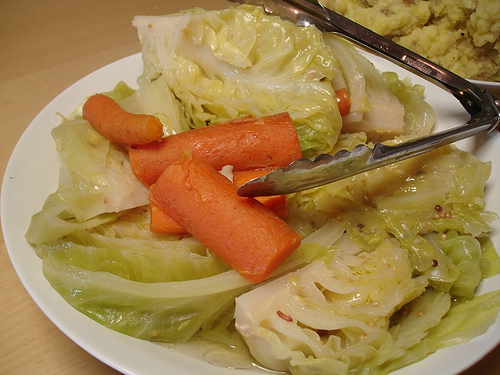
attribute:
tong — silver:
[238, 0, 499, 198]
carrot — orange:
[81, 92, 163, 144]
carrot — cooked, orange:
[151, 150, 302, 284]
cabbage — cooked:
[132, 5, 343, 163]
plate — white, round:
[1, 43, 498, 374]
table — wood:
[0, 0, 499, 373]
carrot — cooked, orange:
[128, 111, 303, 187]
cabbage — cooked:
[233, 226, 452, 374]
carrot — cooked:
[148, 165, 289, 234]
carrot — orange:
[335, 88, 352, 116]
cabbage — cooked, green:
[38, 240, 319, 344]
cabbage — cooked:
[374, 159, 499, 287]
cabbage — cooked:
[54, 76, 193, 221]